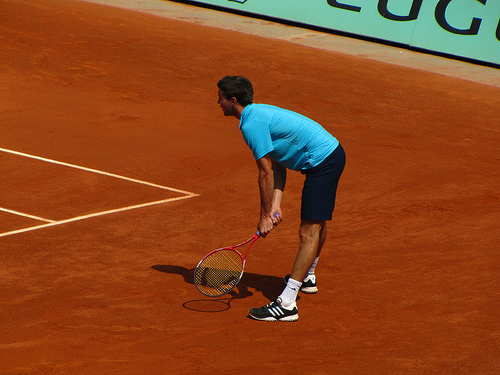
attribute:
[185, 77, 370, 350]
man — bent, playing, holding, playing tennis, bending, gripping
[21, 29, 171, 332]
tennis court — brown, dirt, red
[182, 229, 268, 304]
tennis racket — red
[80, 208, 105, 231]
lines — white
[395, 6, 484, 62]
advertisement — large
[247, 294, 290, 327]
shoe — black, tennis shoes, adidas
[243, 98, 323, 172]
shirt — blue, teal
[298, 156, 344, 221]
shorts — black, navy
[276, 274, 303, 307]
socks — white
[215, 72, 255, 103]
hair — short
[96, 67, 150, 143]
ground — red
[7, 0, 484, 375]
photo — taken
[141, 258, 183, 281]
shadow — cast